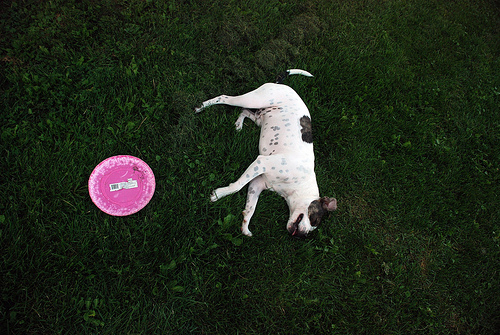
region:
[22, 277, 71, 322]
PAtch of dark green grass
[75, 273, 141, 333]
PAtch of dark green grass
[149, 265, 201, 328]
PAtch of dark green grass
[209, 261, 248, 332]
PAtch of dark green grass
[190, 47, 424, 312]
Dog laying in the grass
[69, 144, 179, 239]
Pink frisbee in the grass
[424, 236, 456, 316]
PAtch of dark green grass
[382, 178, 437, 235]
PAtch of dark green grass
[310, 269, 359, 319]
PAtch of dark green grass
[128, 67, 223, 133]
PAtch of dark green grass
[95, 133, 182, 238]
a rose object in ground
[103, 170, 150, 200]
a small white paper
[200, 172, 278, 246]
front legs of the dog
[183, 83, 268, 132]
back legs of the dog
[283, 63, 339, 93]
tail of the dog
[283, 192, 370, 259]
face of the dog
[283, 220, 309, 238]
mouth of the dog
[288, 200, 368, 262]
a dog opening its mouth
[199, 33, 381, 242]
a dog lying in ground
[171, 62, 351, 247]
a dog sleeping n ground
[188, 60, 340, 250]
dog is on ground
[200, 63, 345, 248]
dog is black and white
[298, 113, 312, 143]
dog has one large spot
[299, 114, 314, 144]
the spot is black in color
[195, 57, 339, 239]
dog is in profile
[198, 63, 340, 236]
dog is laying on grass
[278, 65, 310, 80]
the dog has his tail up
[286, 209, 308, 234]
the dog is panting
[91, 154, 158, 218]
the frisbee is round in shape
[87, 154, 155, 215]
the frisbee is pink in color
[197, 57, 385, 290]
the dog is laying down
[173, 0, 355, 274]
dog is laying on the grass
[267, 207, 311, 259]
the mouth is open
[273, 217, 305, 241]
the tongue is out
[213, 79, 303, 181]
the dog has small spots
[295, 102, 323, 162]
a blackish patch on the dogs back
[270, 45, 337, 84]
tip of the tail is white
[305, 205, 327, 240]
the eye is closed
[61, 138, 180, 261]
a plate on the grass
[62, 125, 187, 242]
the plate is pink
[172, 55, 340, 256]
White and black dog asleep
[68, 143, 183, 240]
Pink plate in the grass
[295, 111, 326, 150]
Small black spot of fur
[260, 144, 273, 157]
Small black spot of fur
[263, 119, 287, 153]
Small black spot of fur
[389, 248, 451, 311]
Small patch of green grass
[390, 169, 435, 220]
Small patch of green grass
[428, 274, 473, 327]
Small patch of green grass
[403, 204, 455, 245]
Small patch of green grass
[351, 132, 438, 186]
Small patch of green grass